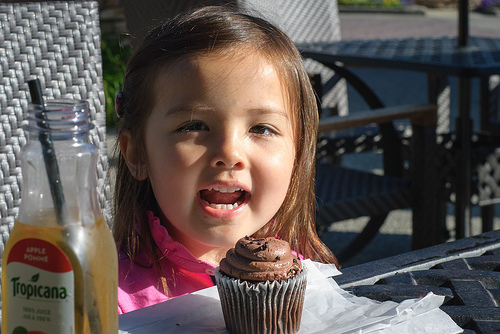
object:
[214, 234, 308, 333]
cupcake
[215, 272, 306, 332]
wrapper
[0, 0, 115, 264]
chair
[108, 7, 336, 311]
girl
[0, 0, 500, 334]
patio